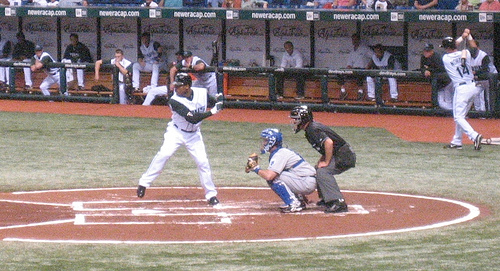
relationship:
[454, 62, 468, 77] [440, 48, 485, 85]
number on shirt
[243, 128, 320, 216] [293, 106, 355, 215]
catcher in front of umpire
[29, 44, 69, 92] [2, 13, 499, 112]
player in dugout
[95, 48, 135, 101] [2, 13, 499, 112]
player in dugout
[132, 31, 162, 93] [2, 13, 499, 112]
player in dugout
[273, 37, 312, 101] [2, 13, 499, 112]
man in dugout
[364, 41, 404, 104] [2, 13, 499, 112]
player in dugout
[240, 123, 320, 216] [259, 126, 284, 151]
catcher wearing helmet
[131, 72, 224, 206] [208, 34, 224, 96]
man swinging bat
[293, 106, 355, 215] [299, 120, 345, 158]
umpire wearing shirt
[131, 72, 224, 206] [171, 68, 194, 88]
man wearing hat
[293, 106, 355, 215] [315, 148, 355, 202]
umpire wearing pants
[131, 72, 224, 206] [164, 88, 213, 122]
man wearing top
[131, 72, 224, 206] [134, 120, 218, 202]
man wearing pants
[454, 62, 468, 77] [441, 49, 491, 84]
number on top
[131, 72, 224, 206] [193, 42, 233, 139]
man holding bat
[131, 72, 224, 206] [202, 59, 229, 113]
man holding bat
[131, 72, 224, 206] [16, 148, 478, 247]
man in dugout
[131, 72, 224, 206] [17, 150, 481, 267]
man in dugout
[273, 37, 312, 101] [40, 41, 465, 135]
man in dugout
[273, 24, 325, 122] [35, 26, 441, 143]
man in dugout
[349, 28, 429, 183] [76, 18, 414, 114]
man in dugout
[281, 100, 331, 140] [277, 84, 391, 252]
helmet on man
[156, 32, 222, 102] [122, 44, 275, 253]
helmet on batter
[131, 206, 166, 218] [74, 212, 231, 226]
home plate next to batter box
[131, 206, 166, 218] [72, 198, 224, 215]
home plate next to batter box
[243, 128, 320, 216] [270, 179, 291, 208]
catcher wearing safety pad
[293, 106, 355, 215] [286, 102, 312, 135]
umpire wearing safety gear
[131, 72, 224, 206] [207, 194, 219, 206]
man wearing footwear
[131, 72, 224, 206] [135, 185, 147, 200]
man wearing footwear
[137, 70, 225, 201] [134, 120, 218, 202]
baseball player wearing pants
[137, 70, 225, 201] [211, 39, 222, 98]
baseball player holding bat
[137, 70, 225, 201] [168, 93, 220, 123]
baseball player wearing sleeves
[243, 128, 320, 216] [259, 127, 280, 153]
catcher wearing helmet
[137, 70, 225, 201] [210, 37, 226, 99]
baseball player swinging bat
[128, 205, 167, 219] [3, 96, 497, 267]
baseball plate in ground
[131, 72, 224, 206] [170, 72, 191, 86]
man wearing helmet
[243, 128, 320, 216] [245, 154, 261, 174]
catcher wearing glove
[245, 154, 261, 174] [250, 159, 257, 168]
glove on hand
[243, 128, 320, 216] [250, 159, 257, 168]
catcher has hand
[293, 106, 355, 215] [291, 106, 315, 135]
umpire wearing hemet